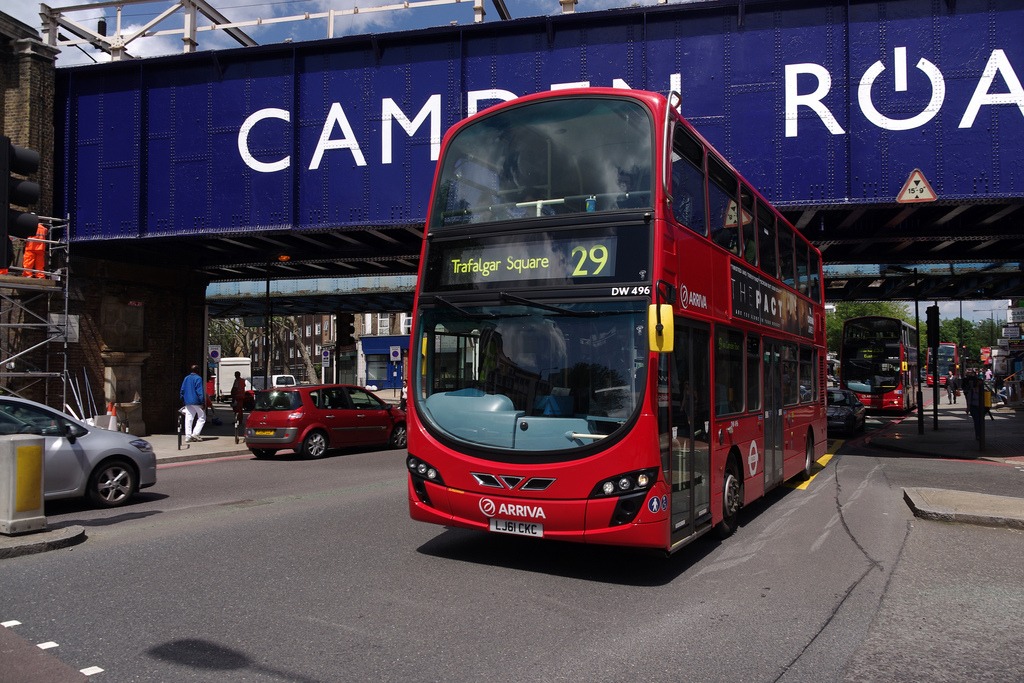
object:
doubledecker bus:
[408, 87, 827, 557]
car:
[244, 385, 406, 459]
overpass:
[54, 0, 1023, 244]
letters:
[235, 46, 1023, 174]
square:
[0, 619, 20, 630]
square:
[36, 641, 60, 652]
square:
[74, 662, 94, 681]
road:
[0, 398, 1024, 683]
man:
[178, 364, 206, 442]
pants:
[184, 405, 206, 440]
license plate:
[488, 518, 542, 538]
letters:
[490, 518, 544, 537]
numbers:
[507, 521, 512, 532]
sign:
[440, 235, 616, 285]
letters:
[451, 256, 549, 277]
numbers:
[572, 245, 608, 277]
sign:
[896, 168, 937, 204]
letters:
[907, 188, 923, 193]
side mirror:
[647, 304, 674, 353]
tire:
[90, 458, 136, 507]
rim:
[98, 467, 133, 502]